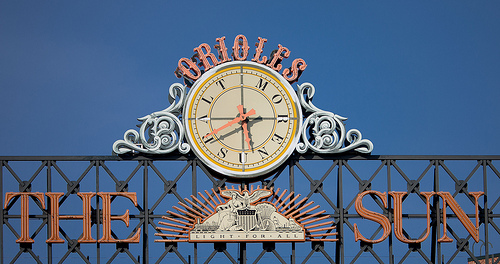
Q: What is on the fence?
A: A clock.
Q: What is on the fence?
A: A clock.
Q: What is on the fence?
A: A metal clock.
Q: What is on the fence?
A: A clock.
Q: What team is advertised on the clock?
A: Baltimore Orioles.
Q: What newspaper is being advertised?
A: Baltimore Sun.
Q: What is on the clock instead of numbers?
A: Letters.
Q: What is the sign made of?
A: Metal.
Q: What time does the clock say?
A: 5:40.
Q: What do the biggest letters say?
A: The Sun.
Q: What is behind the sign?
A: Blue sky.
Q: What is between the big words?
A: Newspaper logo.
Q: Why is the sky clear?
A: No clouds today.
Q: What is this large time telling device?
A: Clock.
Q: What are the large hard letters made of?
A: Metal.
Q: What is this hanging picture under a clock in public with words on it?
A: Sign.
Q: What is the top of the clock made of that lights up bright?
A: Neon.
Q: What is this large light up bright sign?
A: Neon sign.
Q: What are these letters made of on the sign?
A: Wood.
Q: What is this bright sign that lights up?
A: Neon sign.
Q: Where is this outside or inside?
A: Is outside.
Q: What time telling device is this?
A: Clock.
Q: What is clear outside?
A: The weather.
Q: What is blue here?
A: He sky.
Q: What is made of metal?
A: The sign.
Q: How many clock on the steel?
A: One.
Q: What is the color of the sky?
A: Blue.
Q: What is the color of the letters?
A: Orange.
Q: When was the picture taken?
A: Daytime.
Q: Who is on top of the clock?
A: No one.